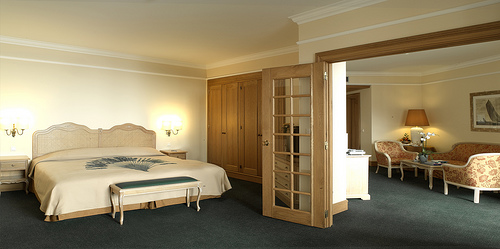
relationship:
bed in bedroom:
[27, 121, 232, 221] [2, 43, 308, 248]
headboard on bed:
[29, 120, 160, 154] [27, 121, 232, 221]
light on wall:
[3, 110, 31, 141] [2, 41, 207, 163]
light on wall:
[162, 114, 182, 137] [2, 41, 207, 163]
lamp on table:
[402, 106, 429, 144] [404, 144, 437, 155]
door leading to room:
[254, 61, 329, 229] [333, 45, 500, 222]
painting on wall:
[469, 90, 499, 131] [424, 62, 499, 151]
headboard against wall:
[29, 120, 160, 154] [2, 41, 207, 163]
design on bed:
[82, 155, 175, 175] [27, 121, 232, 221]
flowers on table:
[417, 128, 434, 160] [397, 157, 446, 190]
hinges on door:
[321, 65, 330, 222] [254, 61, 329, 229]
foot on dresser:
[361, 192, 373, 201] [345, 153, 372, 202]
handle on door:
[261, 138, 269, 146] [254, 61, 329, 229]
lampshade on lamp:
[404, 107, 431, 129] [402, 106, 429, 144]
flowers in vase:
[417, 128, 434, 160] [417, 150, 428, 165]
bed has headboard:
[27, 121, 232, 221] [29, 120, 160, 154]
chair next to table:
[373, 139, 420, 180] [397, 157, 446, 190]